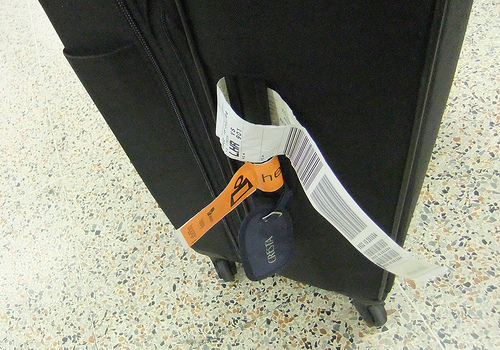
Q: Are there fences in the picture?
A: No, there are no fences.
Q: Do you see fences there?
A: No, there are no fences.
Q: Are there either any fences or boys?
A: No, there are no fences or boys.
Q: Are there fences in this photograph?
A: No, there are no fences.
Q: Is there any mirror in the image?
A: No, there are no mirrors.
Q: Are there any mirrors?
A: No, there are no mirrors.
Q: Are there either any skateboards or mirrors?
A: No, there are no mirrors or skateboards.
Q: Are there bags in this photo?
A: Yes, there is a bag.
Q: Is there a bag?
A: Yes, there is a bag.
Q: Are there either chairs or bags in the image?
A: Yes, there is a bag.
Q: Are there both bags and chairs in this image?
A: No, there is a bag but no chairs.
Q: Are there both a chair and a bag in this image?
A: No, there is a bag but no chairs.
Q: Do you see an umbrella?
A: No, there are no umbrellas.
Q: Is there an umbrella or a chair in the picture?
A: No, there are no umbrellas or chairs.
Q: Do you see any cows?
A: No, there are no cows.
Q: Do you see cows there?
A: No, there are no cows.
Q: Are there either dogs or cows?
A: No, there are no cows or dogs.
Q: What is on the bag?
A: The tag is on the bag.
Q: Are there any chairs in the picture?
A: No, there are no chairs.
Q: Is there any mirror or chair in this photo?
A: No, there are no chairs or mirrors.